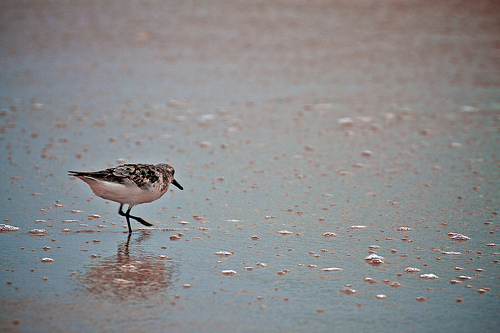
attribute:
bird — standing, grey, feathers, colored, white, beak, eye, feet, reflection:
[68, 120, 198, 265]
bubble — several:
[335, 104, 364, 141]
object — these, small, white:
[362, 224, 400, 278]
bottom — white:
[99, 175, 171, 212]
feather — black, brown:
[92, 170, 119, 194]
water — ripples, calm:
[90, 91, 146, 137]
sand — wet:
[269, 95, 287, 122]